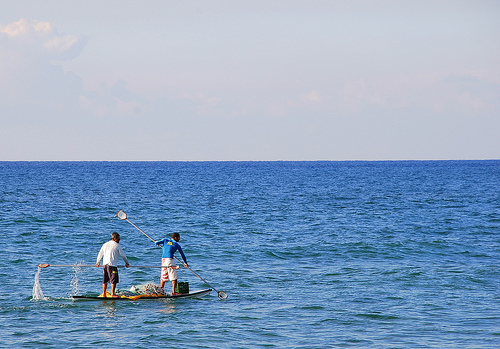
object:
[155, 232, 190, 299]
man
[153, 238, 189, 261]
shirt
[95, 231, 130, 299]
man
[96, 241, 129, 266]
shirt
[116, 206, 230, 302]
paddle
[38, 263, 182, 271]
paddle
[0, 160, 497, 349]
ocean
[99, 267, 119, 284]
shorts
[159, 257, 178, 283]
shorts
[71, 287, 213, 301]
surfboard